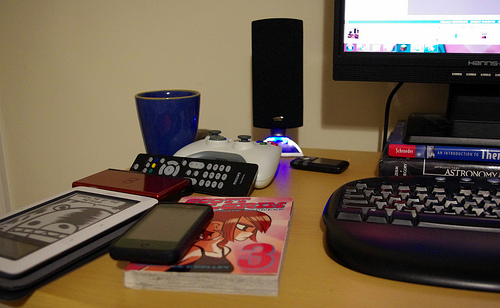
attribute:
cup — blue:
[132, 86, 203, 160]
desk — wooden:
[4, 128, 492, 301]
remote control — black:
[128, 150, 261, 199]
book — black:
[374, 153, 498, 187]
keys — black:
[395, 183, 489, 217]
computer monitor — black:
[329, 0, 498, 81]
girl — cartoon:
[165, 205, 277, 272]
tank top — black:
[159, 240, 233, 272]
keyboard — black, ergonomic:
[322, 174, 498, 256]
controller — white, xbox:
[164, 133, 281, 188]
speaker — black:
[248, 13, 303, 130]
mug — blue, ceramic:
[137, 87, 204, 155]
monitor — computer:
[335, 3, 495, 138]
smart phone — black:
[116, 204, 215, 264]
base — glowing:
[253, 125, 307, 161]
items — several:
[1, 2, 498, 305]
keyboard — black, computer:
[322, 177, 496, 278]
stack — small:
[379, 139, 495, 183]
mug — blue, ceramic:
[131, 88, 200, 159]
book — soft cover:
[122, 194, 292, 293]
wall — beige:
[1, 0, 449, 217]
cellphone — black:
[107, 200, 212, 267]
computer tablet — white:
[0, 184, 159, 281]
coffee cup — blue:
[133, 88, 201, 158]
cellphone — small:
[289, 151, 351, 173]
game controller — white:
[172, 131, 280, 187]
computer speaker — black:
[248, 16, 306, 156]